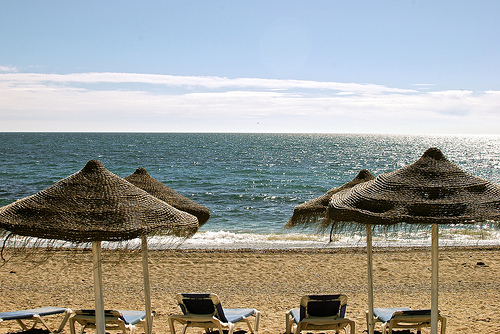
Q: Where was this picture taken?
A: At a beach.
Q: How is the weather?
A: Sunny.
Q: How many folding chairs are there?
A: Five.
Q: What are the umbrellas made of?
A: Grass.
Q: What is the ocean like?
A: Calm.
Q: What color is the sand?
A: Yellowish brown.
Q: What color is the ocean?
A: Dark Blue.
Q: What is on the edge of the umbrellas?
A: Fringe.